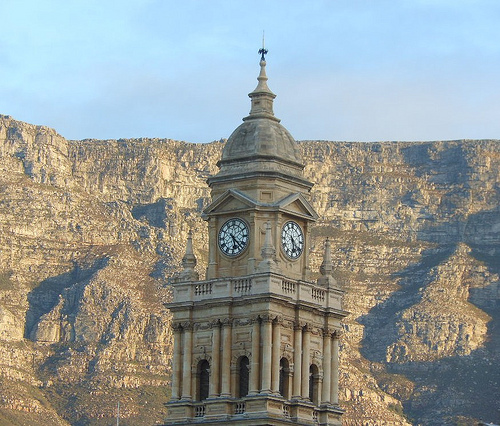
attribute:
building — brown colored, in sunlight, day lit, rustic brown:
[162, 30, 348, 424]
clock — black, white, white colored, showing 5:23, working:
[219, 219, 248, 257]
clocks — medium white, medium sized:
[218, 218, 304, 262]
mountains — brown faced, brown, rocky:
[0, 112, 499, 425]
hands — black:
[228, 231, 244, 250]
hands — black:
[289, 235, 299, 256]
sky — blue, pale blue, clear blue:
[0, 0, 497, 144]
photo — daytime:
[2, 1, 498, 425]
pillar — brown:
[257, 313, 273, 397]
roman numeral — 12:
[230, 219, 238, 227]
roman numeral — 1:
[235, 221, 240, 227]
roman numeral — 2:
[239, 225, 245, 233]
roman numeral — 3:
[240, 232, 248, 238]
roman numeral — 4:
[239, 240, 247, 246]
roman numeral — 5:
[235, 244, 241, 252]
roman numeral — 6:
[229, 248, 235, 256]